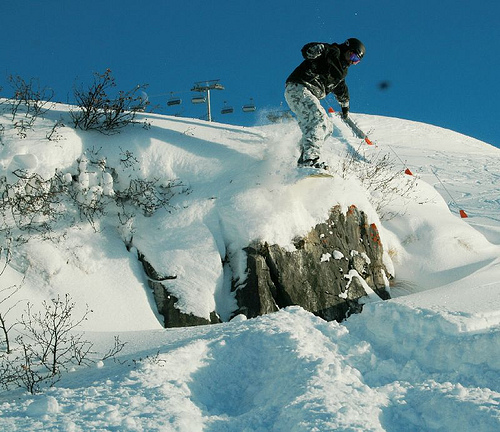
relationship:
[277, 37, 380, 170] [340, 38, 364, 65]
man wearing helmet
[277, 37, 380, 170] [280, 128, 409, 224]
snowboarder going down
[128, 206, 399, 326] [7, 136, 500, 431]
rock wall on slope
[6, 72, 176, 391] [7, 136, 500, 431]
bushes in snow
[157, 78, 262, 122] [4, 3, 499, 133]
ski lift on top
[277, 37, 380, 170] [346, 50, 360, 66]
man wearing goggles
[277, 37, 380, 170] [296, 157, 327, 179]
person on snowboard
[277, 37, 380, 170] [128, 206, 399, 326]
snowboarder on rock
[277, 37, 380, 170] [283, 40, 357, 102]
person wearing jacket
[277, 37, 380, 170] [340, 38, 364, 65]
person wearing helmet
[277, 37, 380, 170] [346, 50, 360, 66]
person wearing goggles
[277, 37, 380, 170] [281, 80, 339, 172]
person wearing snowpants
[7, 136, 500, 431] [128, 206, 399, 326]
snow covering rock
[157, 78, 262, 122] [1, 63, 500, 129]
ski lift in distance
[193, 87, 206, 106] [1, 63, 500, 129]
chair in distance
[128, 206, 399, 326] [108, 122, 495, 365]
rock on slop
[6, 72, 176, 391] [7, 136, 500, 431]
shrubs on mountain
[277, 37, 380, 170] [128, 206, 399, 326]
snowboarder jumping off rock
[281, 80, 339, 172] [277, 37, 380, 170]
pants on man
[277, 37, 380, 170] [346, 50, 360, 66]
snowboarders wearing goggles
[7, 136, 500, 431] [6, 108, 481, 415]
snow covering ground